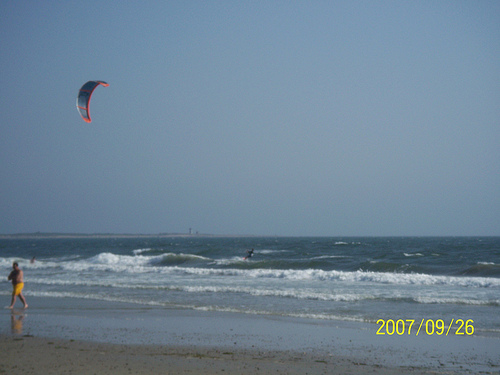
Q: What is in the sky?
A: A parachute.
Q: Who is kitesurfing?
A: The person in the water.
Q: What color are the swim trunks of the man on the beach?
A: Yellow.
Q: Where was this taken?
A: At the beach.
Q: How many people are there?
A: Two.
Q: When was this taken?
A: During the day.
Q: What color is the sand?
A: Dark brown.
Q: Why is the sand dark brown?
A: It is wet.